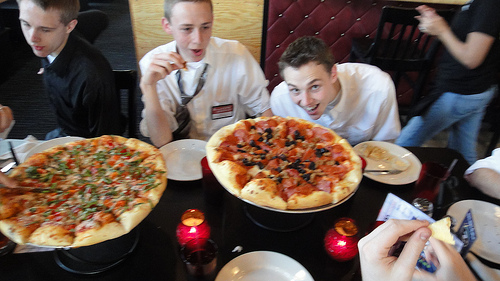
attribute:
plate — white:
[351, 132, 425, 179]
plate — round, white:
[141, 120, 226, 178]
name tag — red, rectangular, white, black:
[203, 100, 239, 125]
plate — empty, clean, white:
[350, 136, 425, 184]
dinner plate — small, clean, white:
[168, 144, 205, 189]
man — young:
[268, 37, 399, 143]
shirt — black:
[16, 2, 136, 139]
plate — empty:
[214, 250, 313, 279]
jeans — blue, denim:
[394, 89, 499, 156]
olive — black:
[242, 119, 339, 184]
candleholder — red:
[176, 209, 206, 241]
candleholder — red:
[324, 218, 355, 258]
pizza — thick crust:
[200, 93, 372, 239]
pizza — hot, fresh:
[204, 117, 367, 212]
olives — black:
[281, 155, 303, 169]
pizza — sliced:
[209, 113, 359, 210]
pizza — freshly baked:
[188, 99, 368, 234]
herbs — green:
[30, 155, 144, 233]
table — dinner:
[62, 145, 382, 271]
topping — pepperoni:
[263, 152, 285, 173]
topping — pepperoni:
[276, 174, 313, 190]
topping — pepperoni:
[302, 138, 324, 166]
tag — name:
[199, 94, 239, 127]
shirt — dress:
[126, 36, 276, 139]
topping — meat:
[306, 177, 341, 196]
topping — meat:
[234, 124, 253, 142]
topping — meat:
[282, 119, 305, 139]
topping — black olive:
[291, 158, 308, 171]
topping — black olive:
[244, 132, 262, 155]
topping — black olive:
[260, 161, 293, 181]